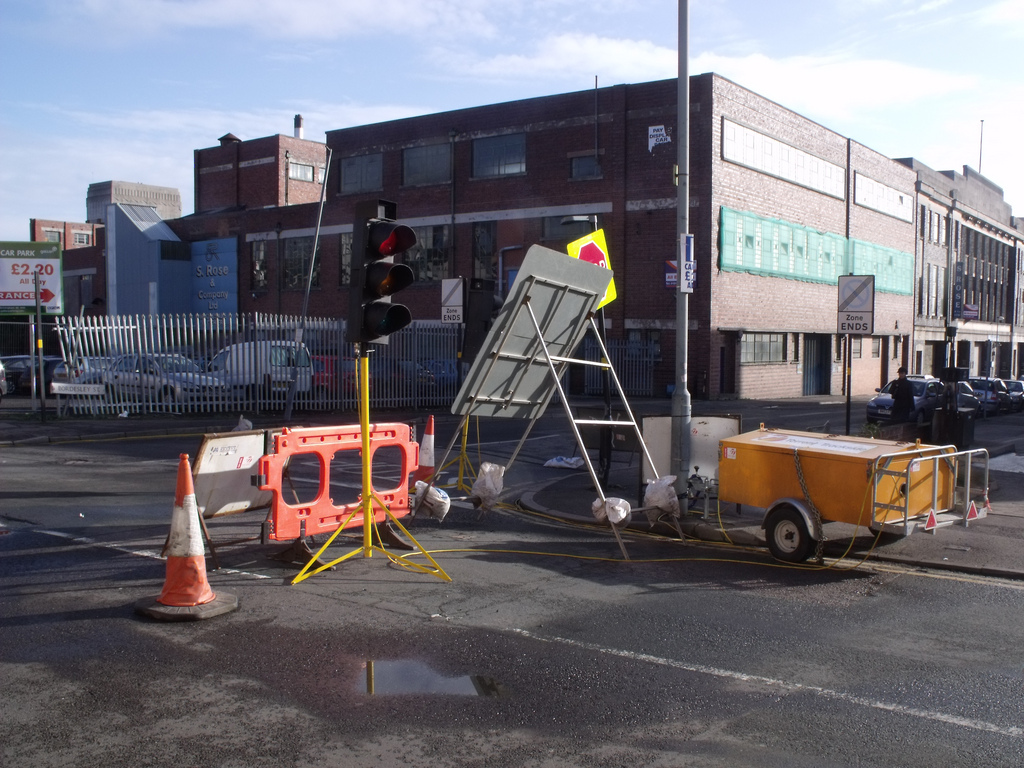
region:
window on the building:
[571, 157, 600, 184]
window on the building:
[735, 332, 768, 372]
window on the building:
[756, 337, 786, 366]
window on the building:
[560, 154, 608, 189]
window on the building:
[476, 139, 518, 178]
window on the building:
[424, 221, 466, 259]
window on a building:
[199, 155, 231, 175]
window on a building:
[234, 149, 282, 172]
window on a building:
[285, 157, 312, 183]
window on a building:
[335, 151, 386, 193]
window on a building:
[400, 146, 457, 185]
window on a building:
[468, 130, 526, 170]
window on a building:
[465, 220, 497, 291]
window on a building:
[540, 209, 573, 232]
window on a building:
[740, 331, 783, 360]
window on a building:
[871, 337, 888, 361]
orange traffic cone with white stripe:
[120, 449, 237, 620]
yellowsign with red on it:
[562, 228, 614, 315]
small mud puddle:
[357, 654, 500, 696]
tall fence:
[50, 318, 461, 414]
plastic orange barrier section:
[255, 418, 420, 540]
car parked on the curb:
[862, 373, 949, 427]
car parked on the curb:
[1002, 380, 1019, 412]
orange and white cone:
[123, 452, 261, 645]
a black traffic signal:
[340, 180, 420, 368]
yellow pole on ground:
[278, 356, 462, 614]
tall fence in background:
[46, 310, 337, 432]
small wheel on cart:
[755, 497, 819, 565]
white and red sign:
[0, 256, 68, 327]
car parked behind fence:
[85, 341, 242, 415]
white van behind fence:
[208, 329, 319, 396]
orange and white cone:
[416, 410, 437, 486]